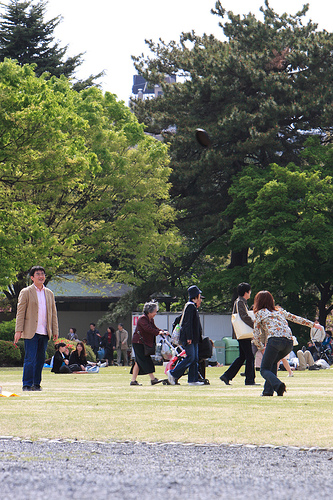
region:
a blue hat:
[186, 283, 202, 299]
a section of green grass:
[2, 366, 327, 445]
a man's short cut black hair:
[235, 280, 253, 300]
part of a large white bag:
[230, 297, 258, 339]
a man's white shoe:
[166, 368, 174, 386]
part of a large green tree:
[192, 134, 328, 316]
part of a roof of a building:
[44, 273, 136, 297]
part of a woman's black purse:
[135, 321, 156, 356]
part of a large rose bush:
[53, 336, 95, 362]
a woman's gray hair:
[141, 300, 159, 316]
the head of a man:
[21, 247, 63, 310]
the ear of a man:
[18, 269, 37, 288]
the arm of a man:
[13, 283, 35, 348]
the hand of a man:
[6, 317, 33, 350]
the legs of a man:
[10, 330, 77, 389]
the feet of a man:
[13, 367, 77, 412]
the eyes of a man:
[23, 265, 56, 283]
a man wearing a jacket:
[13, 198, 106, 357]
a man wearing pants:
[5, 323, 74, 396]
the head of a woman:
[244, 257, 308, 336]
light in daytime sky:
[0, 0, 331, 90]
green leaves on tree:
[236, 165, 327, 299]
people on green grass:
[0, 268, 323, 439]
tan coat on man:
[15, 287, 57, 338]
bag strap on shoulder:
[171, 301, 199, 343]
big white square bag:
[232, 298, 254, 339]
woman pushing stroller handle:
[131, 301, 179, 385]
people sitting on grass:
[51, 342, 93, 372]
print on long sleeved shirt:
[251, 308, 313, 347]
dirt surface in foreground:
[0, 444, 330, 499]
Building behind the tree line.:
[121, 62, 194, 126]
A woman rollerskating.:
[243, 286, 324, 423]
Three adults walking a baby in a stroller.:
[115, 284, 218, 391]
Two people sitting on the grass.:
[51, 337, 103, 380]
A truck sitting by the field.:
[127, 310, 250, 371]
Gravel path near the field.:
[27, 395, 280, 498]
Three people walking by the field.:
[78, 319, 129, 367]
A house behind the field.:
[7, 236, 183, 371]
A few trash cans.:
[206, 329, 247, 364]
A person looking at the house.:
[62, 321, 82, 342]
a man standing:
[12, 264, 76, 401]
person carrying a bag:
[231, 315, 246, 339]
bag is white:
[232, 314, 250, 337]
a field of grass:
[120, 389, 264, 440]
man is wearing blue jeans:
[24, 343, 42, 381]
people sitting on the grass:
[54, 344, 92, 374]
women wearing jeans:
[267, 341, 286, 356]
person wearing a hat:
[187, 283, 199, 295]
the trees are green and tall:
[262, 202, 321, 251]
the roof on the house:
[60, 282, 81, 293]